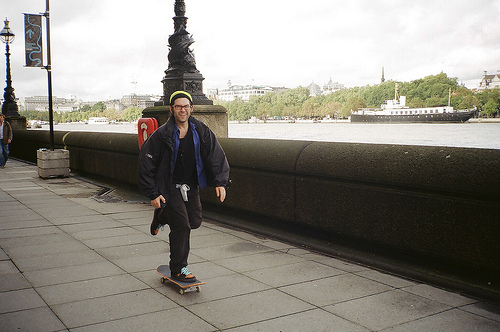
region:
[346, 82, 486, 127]
A large boat in the water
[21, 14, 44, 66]
A flag with blue squiggly lines and an arrow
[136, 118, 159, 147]
A red object with some white on a stone bridge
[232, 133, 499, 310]
Part of a bridge wall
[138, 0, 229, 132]
A gray statue on the edge of the bridge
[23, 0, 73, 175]
A pole with a flag on the walkway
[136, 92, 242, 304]
A man skateboarding on the bridge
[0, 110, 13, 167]
A person walking in the background on the left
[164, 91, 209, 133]
A man smiling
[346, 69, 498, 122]
A cluster of trees in the distance on the right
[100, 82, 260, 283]
man on skateboard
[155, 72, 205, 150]
man wearing green and black beanie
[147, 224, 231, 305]
man wearing orange and black sneakers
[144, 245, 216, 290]
mans sneakers have green laces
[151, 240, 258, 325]
black and orange skateboard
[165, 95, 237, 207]
man wearing blue shirt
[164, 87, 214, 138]
man wearing black rimmed glasses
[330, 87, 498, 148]
boat on the water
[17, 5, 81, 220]
flag on flag post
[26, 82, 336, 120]
buildings in the background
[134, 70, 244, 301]
young man on skateboard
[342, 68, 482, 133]
a boat on the river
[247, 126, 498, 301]
a wall between the sidewalk and the river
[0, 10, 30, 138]
a light along the river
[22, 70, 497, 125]
trees lining the river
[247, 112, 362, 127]
boats along the shore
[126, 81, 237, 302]
one foot on a skateboard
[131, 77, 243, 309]
man with a stocking cap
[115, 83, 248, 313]
man wearing glasses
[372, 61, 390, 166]
a tower across the river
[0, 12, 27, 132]
Light pole with light shown on top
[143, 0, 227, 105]
Light pole where lamp is not visible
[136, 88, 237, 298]
The man riding the skateboard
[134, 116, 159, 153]
Orange square hanging on the wall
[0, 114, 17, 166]
The man shown walking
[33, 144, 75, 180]
Large white box on the sidewalk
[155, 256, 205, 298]
The skater's board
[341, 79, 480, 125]
Large ship in the background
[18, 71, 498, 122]
Trees in the background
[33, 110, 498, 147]
River behind the wall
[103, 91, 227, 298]
man riding on skateboard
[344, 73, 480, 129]
large ship on canal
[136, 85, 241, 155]
smiling man on skateboard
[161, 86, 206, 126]
man wearing knit cap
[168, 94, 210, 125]
man wearing eyeglasses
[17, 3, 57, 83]
banner on lamp pole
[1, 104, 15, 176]
person walking near lamp post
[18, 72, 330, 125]
buildings on hills across canal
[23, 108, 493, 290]
concrete wall along canal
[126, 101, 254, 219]
man wearing dark blue jacket